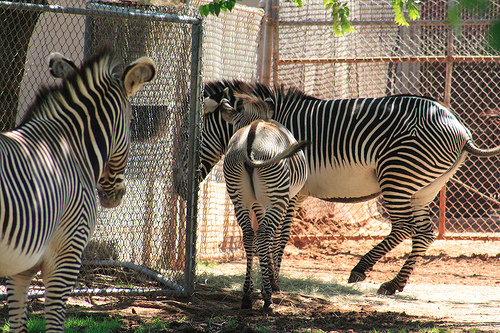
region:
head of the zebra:
[52, 38, 164, 225]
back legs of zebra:
[238, 234, 308, 309]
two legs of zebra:
[358, 220, 440, 276]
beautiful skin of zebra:
[300, 97, 441, 151]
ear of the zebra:
[122, 66, 161, 92]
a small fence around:
[30, 21, 195, 268]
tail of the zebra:
[246, 145, 308, 167]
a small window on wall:
[126, 107, 176, 156]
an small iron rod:
[436, 201, 464, 238]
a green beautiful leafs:
[318, 4, 376, 39]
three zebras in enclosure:
[0, 44, 490, 326]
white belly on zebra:
[306, 158, 377, 210]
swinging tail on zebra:
[242, 130, 312, 175]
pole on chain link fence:
[132, 3, 212, 38]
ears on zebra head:
[35, 42, 175, 100]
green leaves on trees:
[319, 4, 356, 40]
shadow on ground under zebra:
[212, 268, 367, 305]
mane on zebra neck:
[235, 74, 310, 103]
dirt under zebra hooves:
[213, 299, 300, 323]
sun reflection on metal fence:
[212, 13, 257, 62]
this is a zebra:
[214, 100, 304, 277]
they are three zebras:
[18, 55, 473, 290]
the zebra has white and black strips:
[341, 102, 379, 131]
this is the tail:
[466, 141, 498, 151]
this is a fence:
[155, 41, 187, 256]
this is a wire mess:
[381, 50, 431, 70]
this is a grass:
[80, 311, 115, 323]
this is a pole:
[185, 25, 195, 250]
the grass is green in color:
[80, 315, 100, 322]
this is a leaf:
[190, 2, 230, 12]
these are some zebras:
[12, 55, 466, 321]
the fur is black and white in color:
[330, 125, 380, 165]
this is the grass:
[76, 315, 110, 330]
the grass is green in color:
[68, 311, 111, 328]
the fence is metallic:
[151, 32, 191, 267]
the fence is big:
[136, 100, 183, 265]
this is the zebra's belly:
[321, 155, 373, 196]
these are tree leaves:
[327, 3, 496, 40]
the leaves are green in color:
[331, 2, 357, 36]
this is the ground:
[437, 255, 490, 283]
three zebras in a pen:
[3, 37, 499, 322]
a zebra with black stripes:
[0, 36, 177, 326]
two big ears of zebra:
[38, 41, 168, 96]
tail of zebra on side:
[231, 120, 317, 177]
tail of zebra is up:
[461, 122, 498, 160]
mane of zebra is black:
[204, 75, 323, 105]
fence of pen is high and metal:
[136, 0, 219, 283]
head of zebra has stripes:
[53, 45, 164, 214]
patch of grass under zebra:
[7, 302, 172, 327]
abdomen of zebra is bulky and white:
[304, 167, 366, 209]